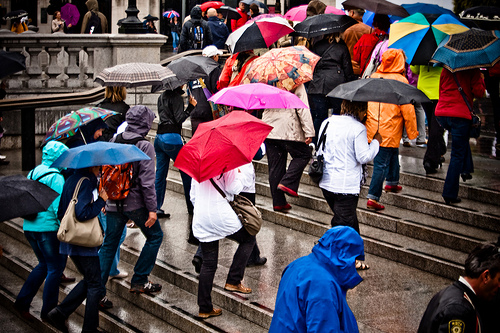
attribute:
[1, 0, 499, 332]
large crowd — walking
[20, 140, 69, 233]
blue rain jacket — bright, enclosing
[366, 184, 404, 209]
red shoes — flat, bright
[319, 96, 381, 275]
woman — half barefoot, wearing, carrying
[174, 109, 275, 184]
reddish umbrella — patterned, white, black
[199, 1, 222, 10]
an umbrella — red, black, green, yellow, blue, abstract, printed, tan and black plaid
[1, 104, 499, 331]
stairs — stone, gray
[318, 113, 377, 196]
jacket — white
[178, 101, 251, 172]
umbrella — colorful 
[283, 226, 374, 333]
jacket — blue and hooded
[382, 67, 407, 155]
raincoat — orange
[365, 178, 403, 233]
shoes — red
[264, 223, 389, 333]
jacket — blue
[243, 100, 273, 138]
umbrella — pink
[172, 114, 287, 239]
umbrella — red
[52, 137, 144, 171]
umbrella — blue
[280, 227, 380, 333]
windbreaker — blue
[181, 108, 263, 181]
umbrella — red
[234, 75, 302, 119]
umbrella — pink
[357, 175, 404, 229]
shoes — red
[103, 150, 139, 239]
bag — red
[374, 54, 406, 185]
coat — orange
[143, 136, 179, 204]
bag — blue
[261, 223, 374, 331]
jacket — blue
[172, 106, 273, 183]
umbrella — red